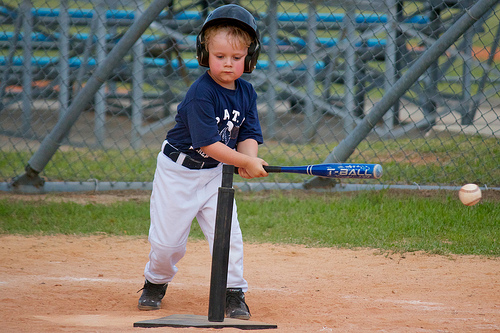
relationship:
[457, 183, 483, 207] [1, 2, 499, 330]
baseball in air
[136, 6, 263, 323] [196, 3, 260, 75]
boy wearing a helmet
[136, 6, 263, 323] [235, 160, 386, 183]
boy swinging a bat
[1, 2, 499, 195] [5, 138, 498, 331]
fence behind field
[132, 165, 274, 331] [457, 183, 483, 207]
stand to hold baseball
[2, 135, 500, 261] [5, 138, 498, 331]
grass on field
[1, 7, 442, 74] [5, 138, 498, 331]
bleachers behind field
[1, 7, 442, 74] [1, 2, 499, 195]
bleachers behind fence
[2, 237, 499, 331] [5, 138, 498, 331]
dirt on field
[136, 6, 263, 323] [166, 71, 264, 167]
boy wearing a shirt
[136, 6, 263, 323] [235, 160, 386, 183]
boy holding bat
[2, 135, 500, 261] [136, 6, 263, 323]
grass behind boy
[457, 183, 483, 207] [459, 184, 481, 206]
baseball has baseball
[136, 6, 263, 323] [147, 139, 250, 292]
boy wearing pants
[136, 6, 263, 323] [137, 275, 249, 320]
boy wearing cleats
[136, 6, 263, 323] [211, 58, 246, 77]
boy with pink cheeks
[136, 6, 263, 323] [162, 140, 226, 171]
boy wearing a belt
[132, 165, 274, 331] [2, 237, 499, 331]
stand in dirt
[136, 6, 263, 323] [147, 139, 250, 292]
boy has pants